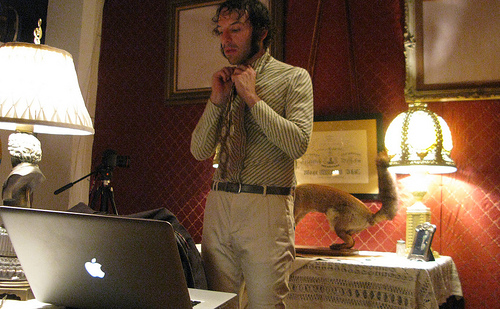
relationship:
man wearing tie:
[201, 10, 316, 263] [222, 115, 250, 151]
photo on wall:
[165, 52, 202, 93] [310, 37, 396, 103]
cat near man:
[326, 192, 376, 235] [201, 10, 316, 263]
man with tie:
[201, 10, 316, 263] [222, 115, 250, 151]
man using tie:
[201, 10, 316, 263] [222, 115, 250, 151]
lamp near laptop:
[385, 108, 453, 176] [9, 206, 182, 299]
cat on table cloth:
[326, 192, 376, 235] [369, 248, 413, 290]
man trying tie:
[201, 10, 316, 263] [222, 115, 250, 151]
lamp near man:
[385, 108, 453, 176] [201, 10, 316, 263]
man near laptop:
[201, 10, 316, 263] [9, 206, 182, 299]